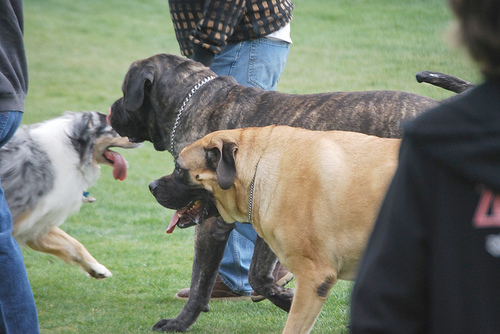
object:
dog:
[148, 124, 405, 334]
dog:
[108, 53, 448, 333]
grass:
[27, 0, 162, 53]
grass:
[298, 0, 448, 69]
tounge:
[104, 149, 129, 181]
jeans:
[1, 107, 41, 334]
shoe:
[173, 273, 252, 303]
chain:
[168, 71, 220, 154]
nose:
[146, 180, 159, 195]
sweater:
[167, 0, 298, 63]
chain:
[245, 164, 257, 225]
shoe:
[249, 261, 295, 303]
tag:
[82, 190, 91, 199]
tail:
[413, 68, 476, 95]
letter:
[471, 188, 496, 228]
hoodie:
[346, 80, 500, 334]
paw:
[150, 318, 192, 333]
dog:
[1, 109, 142, 281]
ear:
[120, 62, 155, 112]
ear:
[201, 140, 239, 191]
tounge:
[163, 205, 189, 234]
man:
[166, 0, 299, 304]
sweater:
[1, 0, 33, 113]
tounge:
[105, 105, 112, 126]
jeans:
[204, 36, 287, 296]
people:
[1, 0, 43, 332]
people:
[346, 0, 499, 334]